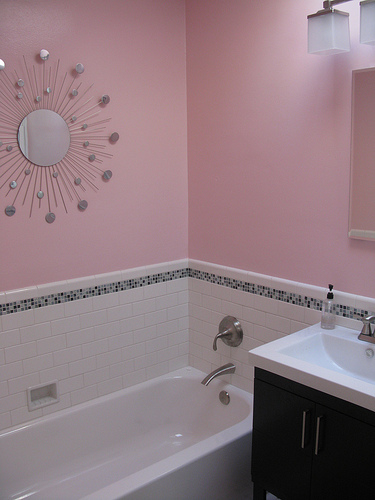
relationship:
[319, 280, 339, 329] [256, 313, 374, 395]
soap on sink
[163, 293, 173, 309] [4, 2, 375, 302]
tile on wall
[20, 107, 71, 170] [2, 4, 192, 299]
mirror hanging on wall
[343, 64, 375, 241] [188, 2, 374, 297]
mirror hanging on wall